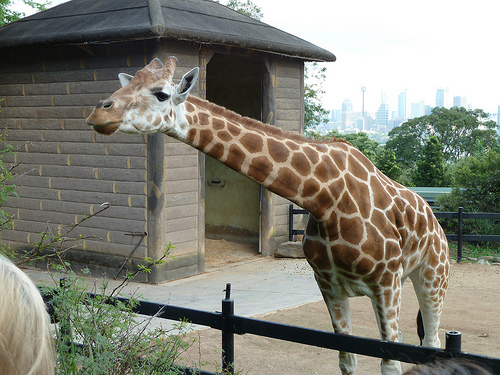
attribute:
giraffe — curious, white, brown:
[73, 44, 454, 373]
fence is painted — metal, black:
[87, 289, 498, 373]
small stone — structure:
[467, 246, 488, 274]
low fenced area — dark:
[439, 208, 498, 259]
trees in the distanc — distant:
[389, 128, 489, 201]